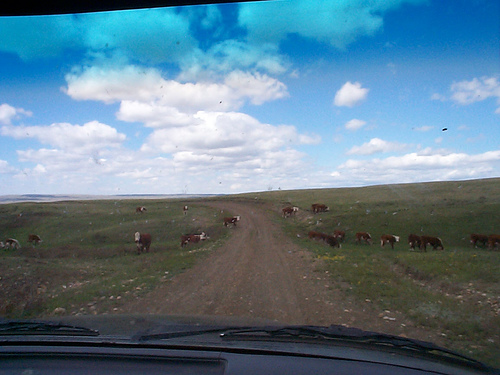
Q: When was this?
A: During the day.